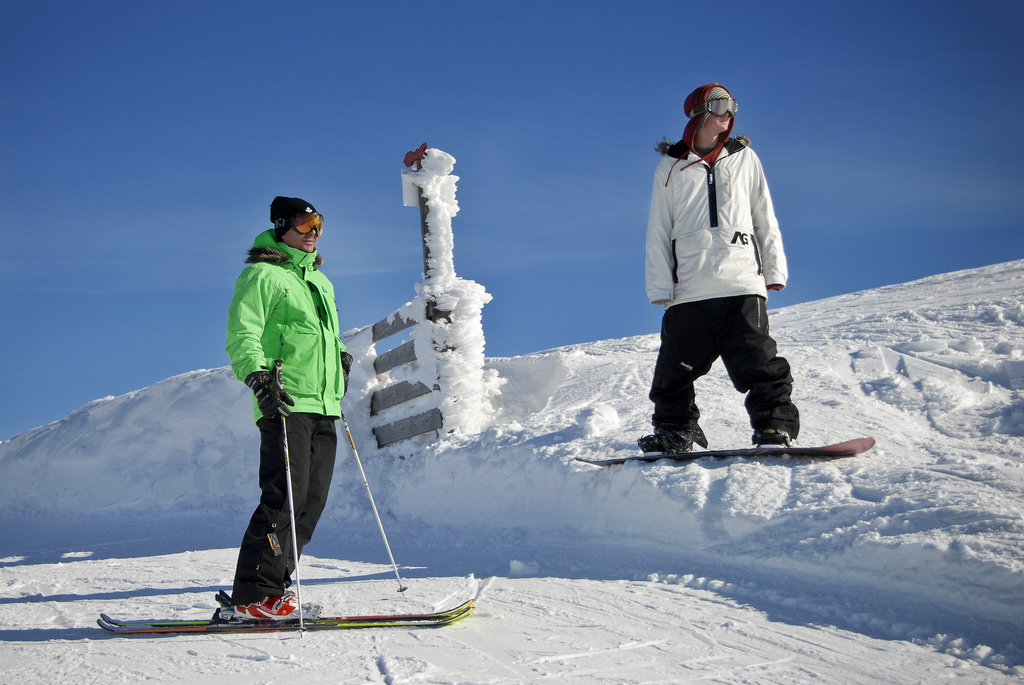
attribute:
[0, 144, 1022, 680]
snow — white